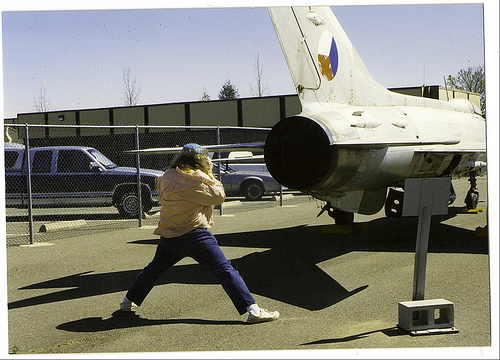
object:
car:
[2, 142, 298, 216]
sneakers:
[120, 302, 137, 311]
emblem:
[317, 31, 339, 82]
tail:
[263, 116, 338, 190]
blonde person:
[120, 143, 279, 323]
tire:
[112, 183, 151, 216]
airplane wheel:
[464, 192, 478, 209]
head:
[169, 143, 216, 180]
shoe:
[247, 308, 279, 323]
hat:
[182, 143, 202, 153]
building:
[0, 85, 482, 170]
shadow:
[6, 205, 489, 345]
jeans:
[126, 228, 257, 315]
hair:
[170, 148, 214, 180]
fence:
[4, 121, 282, 248]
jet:
[264, 6, 486, 234]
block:
[397, 299, 454, 331]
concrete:
[400, 308, 406, 317]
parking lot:
[4, 200, 158, 238]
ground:
[6, 176, 491, 353]